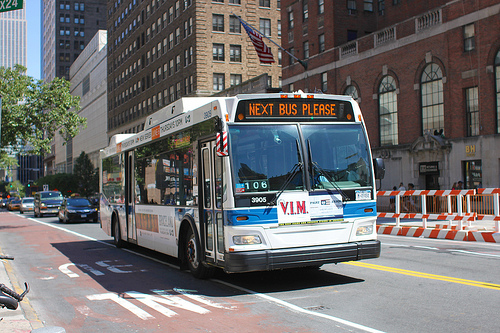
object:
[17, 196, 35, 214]
cars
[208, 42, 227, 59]
windows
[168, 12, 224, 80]
building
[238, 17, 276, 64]
flag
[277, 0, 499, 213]
building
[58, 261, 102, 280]
letters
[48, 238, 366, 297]
shadow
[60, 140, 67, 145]
leaves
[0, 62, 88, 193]
tree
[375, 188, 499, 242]
barriers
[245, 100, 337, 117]
text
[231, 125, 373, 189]
windshield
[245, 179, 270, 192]
number 106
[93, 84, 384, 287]
bus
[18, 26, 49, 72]
sky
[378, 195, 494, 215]
border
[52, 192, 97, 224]
car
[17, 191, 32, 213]
car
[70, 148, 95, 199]
tree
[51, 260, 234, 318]
white text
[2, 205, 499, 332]
street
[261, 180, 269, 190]
numbers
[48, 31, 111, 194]
building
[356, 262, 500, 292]
line